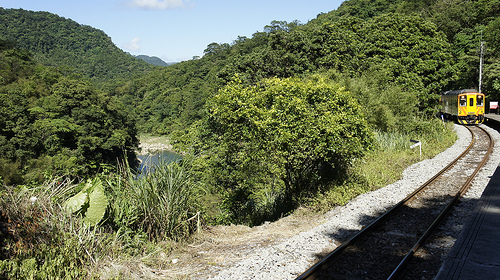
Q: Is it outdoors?
A: Yes, it is outdoors.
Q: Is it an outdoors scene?
A: Yes, it is outdoors.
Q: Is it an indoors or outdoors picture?
A: It is outdoors.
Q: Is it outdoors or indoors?
A: It is outdoors.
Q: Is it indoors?
A: No, it is outdoors.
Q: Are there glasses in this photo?
A: No, there are no glasses.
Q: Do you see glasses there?
A: No, there are no glasses.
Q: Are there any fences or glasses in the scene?
A: No, there are no glasses or fences.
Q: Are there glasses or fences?
A: No, there are no glasses or fences.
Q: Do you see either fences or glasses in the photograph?
A: No, there are no glasses or fences.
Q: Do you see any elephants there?
A: No, there are no elephants.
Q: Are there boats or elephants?
A: No, there are no elephants or boats.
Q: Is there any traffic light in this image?
A: No, there are no traffic lights.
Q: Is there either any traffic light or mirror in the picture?
A: No, there are no traffic lights or mirrors.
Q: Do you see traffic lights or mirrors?
A: No, there are no traffic lights or mirrors.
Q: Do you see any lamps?
A: No, there are no lamps.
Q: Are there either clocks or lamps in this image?
A: No, there are no lamps or clocks.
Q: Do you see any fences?
A: No, there are no fences.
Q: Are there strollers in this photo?
A: No, there are no strollers.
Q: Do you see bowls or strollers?
A: No, there are no strollers or bowls.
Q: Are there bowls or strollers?
A: No, there are no strollers or bowls.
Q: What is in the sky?
A: The clouds are in the sky.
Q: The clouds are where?
A: The clouds are in the sky.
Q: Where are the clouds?
A: The clouds are in the sky.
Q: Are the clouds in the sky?
A: Yes, the clouds are in the sky.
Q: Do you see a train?
A: Yes, there is a train.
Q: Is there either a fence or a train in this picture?
A: Yes, there is a train.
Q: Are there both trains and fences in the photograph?
A: No, there is a train but no fences.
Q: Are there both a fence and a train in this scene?
A: No, there is a train but no fences.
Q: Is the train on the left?
A: No, the train is on the right of the image.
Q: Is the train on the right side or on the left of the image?
A: The train is on the right of the image.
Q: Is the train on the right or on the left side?
A: The train is on the right of the image.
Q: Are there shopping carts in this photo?
A: No, there are no shopping carts.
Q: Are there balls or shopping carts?
A: No, there are no shopping carts or balls.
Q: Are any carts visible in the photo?
A: No, there are no carts.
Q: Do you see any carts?
A: No, there are no carts.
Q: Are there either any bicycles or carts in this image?
A: No, there are no carts or bicycles.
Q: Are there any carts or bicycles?
A: No, there are no carts or bicycles.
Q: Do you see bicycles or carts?
A: No, there are no carts or bicycles.